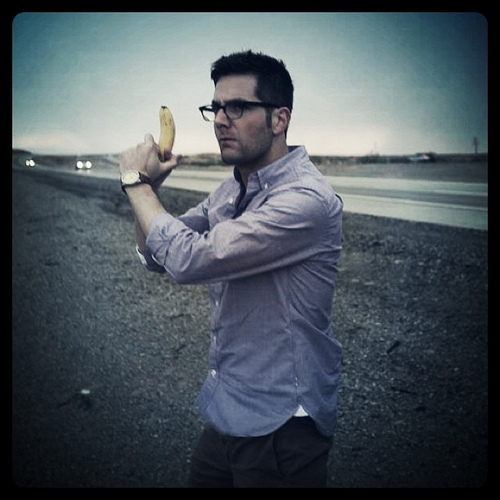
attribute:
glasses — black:
[143, 75, 275, 123]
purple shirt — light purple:
[146, 145, 346, 442]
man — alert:
[122, 48, 364, 496]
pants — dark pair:
[178, 410, 331, 499]